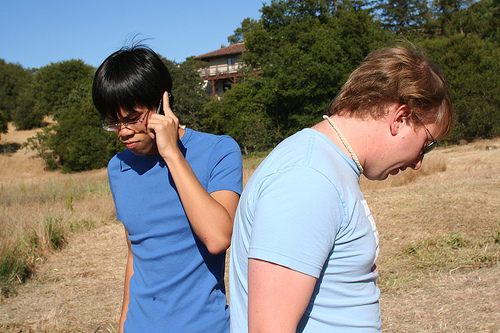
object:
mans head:
[85, 44, 179, 157]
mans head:
[329, 36, 459, 182]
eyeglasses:
[100, 108, 154, 133]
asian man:
[90, 32, 244, 331]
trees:
[223, 0, 323, 150]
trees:
[0, 58, 31, 130]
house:
[183, 36, 300, 105]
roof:
[189, 40, 250, 59]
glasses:
[405, 101, 443, 154]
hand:
[146, 87, 181, 158]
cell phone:
[154, 93, 177, 118]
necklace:
[319, 113, 365, 175]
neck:
[308, 101, 376, 174]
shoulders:
[180, 128, 239, 157]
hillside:
[360, 140, 499, 330]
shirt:
[104, 126, 246, 333]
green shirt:
[225, 128, 384, 333]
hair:
[87, 32, 177, 122]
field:
[0, 124, 500, 331]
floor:
[190, 41, 275, 77]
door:
[226, 54, 235, 71]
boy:
[223, 35, 458, 332]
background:
[0, 0, 499, 153]